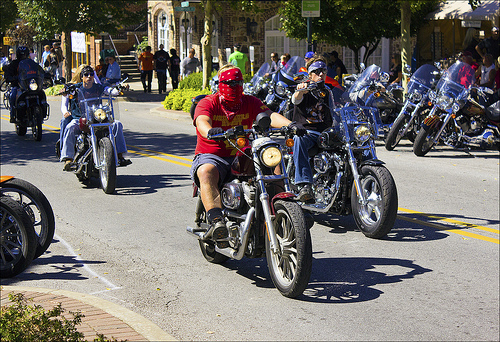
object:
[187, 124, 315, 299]
motorcycle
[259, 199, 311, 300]
wheel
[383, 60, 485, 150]
motorcycles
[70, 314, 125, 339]
bricks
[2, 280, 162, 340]
curb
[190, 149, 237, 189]
short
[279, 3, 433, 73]
trees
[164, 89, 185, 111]
bushes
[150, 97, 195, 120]
corner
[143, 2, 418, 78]
building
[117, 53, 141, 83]
steps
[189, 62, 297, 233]
biker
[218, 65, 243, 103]
mask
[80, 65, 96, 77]
helmet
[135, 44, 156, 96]
adult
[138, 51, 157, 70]
shirt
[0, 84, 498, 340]
street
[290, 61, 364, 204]
man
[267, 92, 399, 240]
motorcycle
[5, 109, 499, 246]
yellow line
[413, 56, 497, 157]
motorcycles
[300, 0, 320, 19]
sign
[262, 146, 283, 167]
headlight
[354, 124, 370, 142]
headlight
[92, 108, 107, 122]
headlight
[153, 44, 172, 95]
person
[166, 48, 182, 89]
person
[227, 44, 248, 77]
person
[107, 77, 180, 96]
sidewalk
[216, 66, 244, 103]
bandana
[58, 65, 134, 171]
biker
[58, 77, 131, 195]
bike